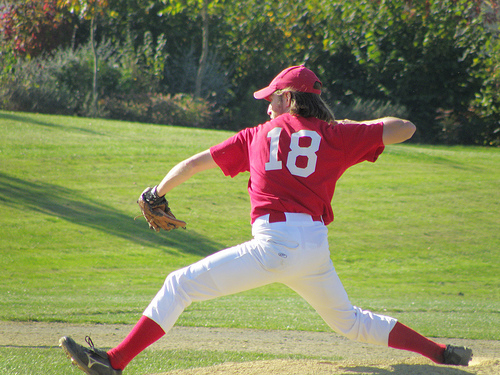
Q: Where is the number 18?
A: On shirt.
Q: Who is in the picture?
A: Pitcher.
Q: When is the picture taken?
A: Day time.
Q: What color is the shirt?
A: Red.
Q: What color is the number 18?
A: White.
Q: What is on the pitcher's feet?
A: Cleats.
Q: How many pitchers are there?
A: One.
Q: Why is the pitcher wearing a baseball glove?
A: Catch ball.